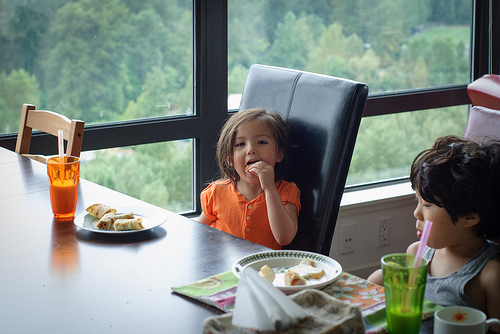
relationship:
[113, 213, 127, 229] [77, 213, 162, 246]
food on plate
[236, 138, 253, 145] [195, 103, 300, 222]
eye of girl